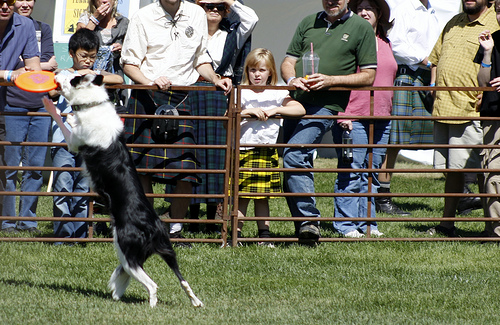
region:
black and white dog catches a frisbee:
[8, 63, 206, 313]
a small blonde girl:
[215, 46, 307, 255]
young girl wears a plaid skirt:
[219, 48, 306, 253]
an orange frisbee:
[10, 68, 63, 96]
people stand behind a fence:
[1, 3, 498, 244]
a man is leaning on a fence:
[274, 0, 380, 247]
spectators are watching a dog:
[2, 1, 498, 307]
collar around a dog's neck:
[67, 95, 115, 116]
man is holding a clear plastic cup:
[277, 1, 380, 246]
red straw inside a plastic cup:
[305, 38, 318, 77]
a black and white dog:
[24, 57, 229, 314]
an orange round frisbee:
[3, 61, 69, 109]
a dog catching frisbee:
[11, 57, 218, 323]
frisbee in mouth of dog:
[15, 64, 103, 118]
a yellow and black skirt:
[218, 141, 307, 209]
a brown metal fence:
[3, 65, 494, 267]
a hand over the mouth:
[83, 0, 141, 43]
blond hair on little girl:
[243, 42, 284, 94]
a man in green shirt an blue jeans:
[278, 7, 384, 283]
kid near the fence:
[52, 30, 122, 243]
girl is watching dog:
[230, 48, 305, 243]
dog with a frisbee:
[14, 68, 205, 312]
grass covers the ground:
[0, 163, 498, 324]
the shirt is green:
[287, 13, 375, 111]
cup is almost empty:
[301, 43, 319, 85]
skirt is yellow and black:
[226, 148, 282, 199]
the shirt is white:
[120, 2, 212, 84]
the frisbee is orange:
[16, 69, 56, 91]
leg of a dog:
[113, 229, 156, 307]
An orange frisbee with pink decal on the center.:
[13, 69, 58, 92]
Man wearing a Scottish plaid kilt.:
[125, 51, 204, 193]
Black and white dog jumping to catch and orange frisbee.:
[13, 67, 202, 310]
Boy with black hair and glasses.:
[66, 29, 101, 71]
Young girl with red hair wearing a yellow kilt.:
[226, 48, 305, 240]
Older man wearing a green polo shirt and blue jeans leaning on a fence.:
[281, 1, 376, 250]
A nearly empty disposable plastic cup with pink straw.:
[300, 42, 321, 84]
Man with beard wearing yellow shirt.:
[436, 0, 498, 124]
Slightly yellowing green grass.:
[1, 240, 499, 322]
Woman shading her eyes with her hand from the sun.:
[194, 0, 256, 48]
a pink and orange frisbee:
[11, 67, 56, 94]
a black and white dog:
[41, 66, 202, 311]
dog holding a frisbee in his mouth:
[12, 62, 204, 312]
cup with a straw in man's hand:
[298, 39, 320, 90]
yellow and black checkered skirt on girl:
[223, 145, 284, 202]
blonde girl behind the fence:
[223, 45, 305, 254]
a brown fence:
[3, 69, 498, 253]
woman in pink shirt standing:
[328, 1, 403, 239]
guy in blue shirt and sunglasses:
[0, 1, 42, 120]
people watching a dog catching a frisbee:
[1, 2, 498, 323]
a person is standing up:
[420, 0, 495, 232]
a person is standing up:
[338, 4, 405, 236]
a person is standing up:
[276, 2, 378, 239]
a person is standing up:
[233, 51, 309, 243]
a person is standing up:
[113, 0, 240, 244]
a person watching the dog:
[224, 41, 326, 228]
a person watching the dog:
[265, 6, 365, 183]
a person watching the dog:
[345, 42, 396, 220]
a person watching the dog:
[74, 32, 106, 149]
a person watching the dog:
[193, 7, 265, 176]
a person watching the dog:
[208, 39, 325, 311]